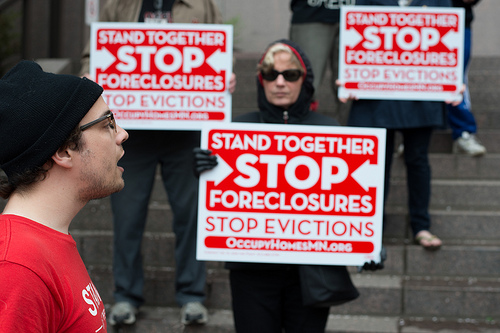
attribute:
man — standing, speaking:
[1, 53, 136, 332]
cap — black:
[0, 55, 113, 194]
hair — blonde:
[254, 37, 309, 83]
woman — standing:
[175, 31, 380, 332]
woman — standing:
[328, 1, 460, 256]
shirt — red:
[1, 208, 110, 332]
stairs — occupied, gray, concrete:
[61, 28, 500, 332]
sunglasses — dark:
[255, 62, 311, 88]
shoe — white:
[446, 127, 489, 161]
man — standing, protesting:
[79, 1, 241, 332]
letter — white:
[113, 41, 142, 78]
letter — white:
[132, 41, 159, 79]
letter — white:
[152, 42, 187, 78]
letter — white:
[178, 41, 209, 77]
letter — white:
[233, 148, 264, 195]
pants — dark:
[353, 117, 444, 241]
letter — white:
[256, 147, 291, 193]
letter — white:
[284, 148, 325, 197]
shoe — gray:
[102, 285, 146, 332]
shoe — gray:
[170, 289, 216, 330]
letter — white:
[316, 152, 353, 197]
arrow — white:
[204, 44, 233, 79]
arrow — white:
[95, 41, 122, 74]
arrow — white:
[346, 153, 379, 196]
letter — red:
[204, 208, 218, 237]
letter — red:
[244, 212, 264, 237]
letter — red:
[259, 212, 280, 240]